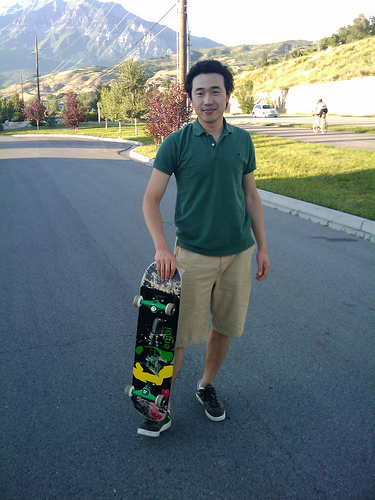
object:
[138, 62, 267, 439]
man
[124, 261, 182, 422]
skateboard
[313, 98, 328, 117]
person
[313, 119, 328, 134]
bicycle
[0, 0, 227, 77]
mountain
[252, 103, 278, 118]
car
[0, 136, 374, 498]
road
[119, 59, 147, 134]
trees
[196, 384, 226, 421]
shoe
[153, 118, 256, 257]
shirt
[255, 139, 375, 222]
grass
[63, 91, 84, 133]
tree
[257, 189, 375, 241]
curb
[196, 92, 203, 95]
eyes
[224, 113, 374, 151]
road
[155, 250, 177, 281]
right hand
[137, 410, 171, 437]
foot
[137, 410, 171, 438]
shoes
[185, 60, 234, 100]
hair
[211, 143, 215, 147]
buttons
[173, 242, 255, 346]
shorts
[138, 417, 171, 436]
trim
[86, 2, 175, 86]
telephone lines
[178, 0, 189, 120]
pole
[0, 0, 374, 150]
background